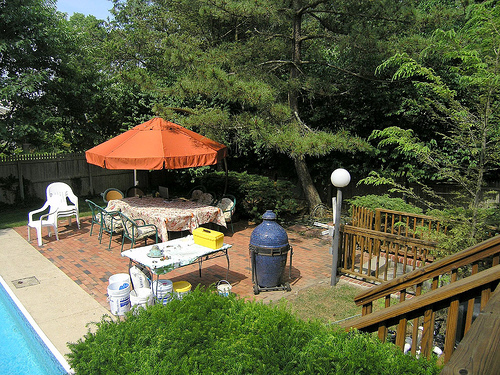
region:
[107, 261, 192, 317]
Group of plastic containers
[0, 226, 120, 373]
Inground Swimming Pool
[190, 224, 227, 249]
Bright Yellow Toolbox On Table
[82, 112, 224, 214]
Large Sunfaded Red Umbrella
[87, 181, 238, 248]
Outdoor Patio Dining Set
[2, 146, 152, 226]
Privacy Fence in the back of the yard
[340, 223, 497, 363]
Wooden Stairs from the back of the house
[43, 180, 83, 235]
Sack of White Lawn Chairs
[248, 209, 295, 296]
Large Blue Cleaning Equipment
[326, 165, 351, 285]
Round Ball Light on Metal Pole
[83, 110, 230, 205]
A large orange parasol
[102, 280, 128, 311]
A white plastic bucket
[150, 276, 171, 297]
A white plastic bucket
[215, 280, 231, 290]
A white plastic bucket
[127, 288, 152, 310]
A white plastic bucket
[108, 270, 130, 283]
A white plastic bucket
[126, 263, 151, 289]
A white plastic bucket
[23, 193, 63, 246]
A white plastic chair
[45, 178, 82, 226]
A stack of white plastic chairs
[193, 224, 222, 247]
A yellow box on a table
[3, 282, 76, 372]
backyard swimming pool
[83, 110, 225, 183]
orange-red umbrella over the dining table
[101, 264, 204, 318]
plastic buckets gathered under table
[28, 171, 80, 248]
stacked white plastic chairs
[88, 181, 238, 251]
green chairs around the dining table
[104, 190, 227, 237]
floral tablecloth over dining table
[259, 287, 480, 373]
small patch of grass beside stairs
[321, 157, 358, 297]
lamp post with white globe light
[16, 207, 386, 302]
brick patio dining area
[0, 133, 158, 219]
high wooden fence to give privacy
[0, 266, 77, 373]
Part of backyard swimming pool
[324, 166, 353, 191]
Round white yard light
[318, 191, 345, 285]
Metal pole of yard light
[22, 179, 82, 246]
White plastic chairs near swimming pool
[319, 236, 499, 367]
Wooden stair railing leading to backyard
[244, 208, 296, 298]
Portable bbq grill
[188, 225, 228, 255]
Yellow box on table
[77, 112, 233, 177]
Orange shade providing umbrella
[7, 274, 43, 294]
Swimming pool access panel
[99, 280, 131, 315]
White plastic bucket on ground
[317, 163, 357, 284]
light on a pole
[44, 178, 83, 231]
stack of white plastic chairs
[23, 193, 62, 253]
white plastic chair near the pool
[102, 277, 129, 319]
white bucket near the pool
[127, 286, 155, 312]
white bucket near the pool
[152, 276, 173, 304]
white bucket near the pool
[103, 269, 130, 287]
white bucket near the pool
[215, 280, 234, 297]
white bucket near the pool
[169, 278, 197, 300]
yellow bucket near the pool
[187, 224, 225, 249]
yellow toolbox on a table